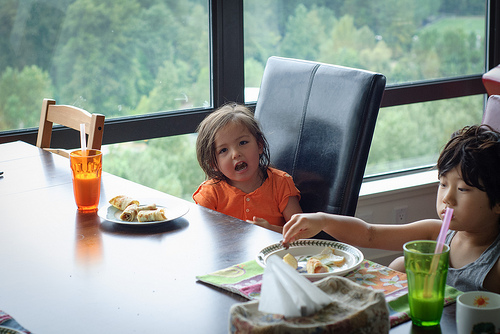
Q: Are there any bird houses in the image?
A: No, there are no bird houses.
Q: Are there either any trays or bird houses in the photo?
A: No, there are no bird houses or trays.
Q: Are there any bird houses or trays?
A: No, there are no bird houses or trays.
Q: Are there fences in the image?
A: No, there are no fences.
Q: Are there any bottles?
A: No, there are no bottles.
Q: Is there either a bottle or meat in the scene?
A: No, there are no bottles or meat.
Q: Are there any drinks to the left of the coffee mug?
A: Yes, there is a drink to the left of the coffee mug.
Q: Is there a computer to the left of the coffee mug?
A: No, there is a drink to the left of the coffee mug.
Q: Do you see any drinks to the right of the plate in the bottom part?
A: Yes, there is a drink to the right of the plate.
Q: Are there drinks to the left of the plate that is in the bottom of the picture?
A: No, the drink is to the right of the plate.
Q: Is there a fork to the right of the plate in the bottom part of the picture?
A: No, there is a drink to the right of the plate.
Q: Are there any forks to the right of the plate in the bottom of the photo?
A: No, there is a drink to the right of the plate.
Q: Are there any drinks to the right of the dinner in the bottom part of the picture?
A: Yes, there is a drink to the right of the dinner.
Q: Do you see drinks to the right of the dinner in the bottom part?
A: Yes, there is a drink to the right of the dinner.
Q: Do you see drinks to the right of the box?
A: Yes, there is a drink to the right of the box.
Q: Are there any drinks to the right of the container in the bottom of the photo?
A: Yes, there is a drink to the right of the box.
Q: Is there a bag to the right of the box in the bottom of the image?
A: No, there is a drink to the right of the box.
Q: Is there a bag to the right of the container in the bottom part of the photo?
A: No, there is a drink to the right of the box.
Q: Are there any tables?
A: Yes, there is a table.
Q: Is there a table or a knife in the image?
A: Yes, there is a table.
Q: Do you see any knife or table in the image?
A: Yes, there is a table.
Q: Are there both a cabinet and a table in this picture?
A: No, there is a table but no cabinets.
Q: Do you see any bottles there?
A: No, there are no bottles.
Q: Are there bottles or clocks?
A: No, there are no bottles or clocks.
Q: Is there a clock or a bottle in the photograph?
A: No, there are no bottles or clocks.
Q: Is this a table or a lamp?
A: This is a table.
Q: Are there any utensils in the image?
A: No, there are no utensils.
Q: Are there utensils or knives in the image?
A: No, there are no utensils or knives.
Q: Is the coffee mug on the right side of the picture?
A: Yes, the coffee mug is on the right of the image.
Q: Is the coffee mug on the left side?
A: No, the coffee mug is on the right of the image.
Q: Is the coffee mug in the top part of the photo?
A: No, the coffee mug is in the bottom of the image.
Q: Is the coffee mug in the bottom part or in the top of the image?
A: The coffee mug is in the bottom of the image.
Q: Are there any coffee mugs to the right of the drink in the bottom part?
A: Yes, there is a coffee mug to the right of the drink.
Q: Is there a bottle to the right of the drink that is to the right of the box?
A: No, there is a coffee mug to the right of the drink.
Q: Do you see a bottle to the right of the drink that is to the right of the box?
A: No, there is a coffee mug to the right of the drink.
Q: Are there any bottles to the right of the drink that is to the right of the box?
A: No, there is a coffee mug to the right of the drink.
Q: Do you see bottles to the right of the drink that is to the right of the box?
A: No, there is a coffee mug to the right of the drink.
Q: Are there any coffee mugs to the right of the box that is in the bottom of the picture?
A: Yes, there is a coffee mug to the right of the box.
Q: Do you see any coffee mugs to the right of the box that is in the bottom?
A: Yes, there is a coffee mug to the right of the box.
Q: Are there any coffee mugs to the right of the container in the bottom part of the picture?
A: Yes, there is a coffee mug to the right of the box.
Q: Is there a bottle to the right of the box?
A: No, there is a coffee mug to the right of the box.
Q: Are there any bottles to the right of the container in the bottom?
A: No, there is a coffee mug to the right of the box.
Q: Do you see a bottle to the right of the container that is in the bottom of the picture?
A: No, there is a coffee mug to the right of the box.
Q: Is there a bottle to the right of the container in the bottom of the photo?
A: No, there is a coffee mug to the right of the box.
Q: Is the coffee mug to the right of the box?
A: Yes, the coffee mug is to the right of the box.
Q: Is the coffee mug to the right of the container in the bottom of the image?
A: Yes, the coffee mug is to the right of the box.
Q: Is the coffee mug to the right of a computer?
A: No, the coffee mug is to the right of the box.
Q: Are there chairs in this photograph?
A: Yes, there is a chair.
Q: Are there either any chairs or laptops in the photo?
A: Yes, there is a chair.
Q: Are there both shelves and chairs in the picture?
A: No, there is a chair but no shelves.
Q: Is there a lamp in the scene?
A: No, there are no lamps.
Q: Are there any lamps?
A: No, there are no lamps.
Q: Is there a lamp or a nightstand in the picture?
A: No, there are no lamps or nightstands.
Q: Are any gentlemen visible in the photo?
A: No, there are no gentlemen.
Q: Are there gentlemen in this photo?
A: No, there are no gentlemen.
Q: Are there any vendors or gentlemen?
A: No, there are no gentlemen or vendors.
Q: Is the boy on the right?
A: Yes, the boy is on the right of the image.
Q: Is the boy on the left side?
A: No, the boy is on the right of the image.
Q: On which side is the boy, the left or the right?
A: The boy is on the right of the image.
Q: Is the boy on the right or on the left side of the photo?
A: The boy is on the right of the image.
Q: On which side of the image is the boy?
A: The boy is on the right of the image.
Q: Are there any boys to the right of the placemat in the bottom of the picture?
A: Yes, there is a boy to the right of the placemat.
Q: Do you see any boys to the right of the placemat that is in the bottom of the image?
A: Yes, there is a boy to the right of the placemat.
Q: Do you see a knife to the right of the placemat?
A: No, there is a boy to the right of the placemat.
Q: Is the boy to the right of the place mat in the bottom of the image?
A: Yes, the boy is to the right of the placemat.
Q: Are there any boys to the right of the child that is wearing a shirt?
A: Yes, there is a boy to the right of the child.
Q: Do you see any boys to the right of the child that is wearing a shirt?
A: Yes, there is a boy to the right of the child.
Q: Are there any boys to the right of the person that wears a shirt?
A: Yes, there is a boy to the right of the child.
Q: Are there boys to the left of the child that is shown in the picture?
A: No, the boy is to the right of the child.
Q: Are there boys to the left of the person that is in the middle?
A: No, the boy is to the right of the child.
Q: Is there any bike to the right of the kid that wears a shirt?
A: No, there is a boy to the right of the kid.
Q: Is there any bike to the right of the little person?
A: No, there is a boy to the right of the kid.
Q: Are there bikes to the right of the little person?
A: No, there is a boy to the right of the kid.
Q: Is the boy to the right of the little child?
A: Yes, the boy is to the right of the kid.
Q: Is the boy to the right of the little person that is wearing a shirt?
A: Yes, the boy is to the right of the kid.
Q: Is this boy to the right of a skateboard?
A: No, the boy is to the right of the kid.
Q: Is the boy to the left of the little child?
A: No, the boy is to the right of the kid.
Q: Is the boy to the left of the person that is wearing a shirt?
A: No, the boy is to the right of the kid.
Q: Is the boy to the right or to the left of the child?
A: The boy is to the right of the child.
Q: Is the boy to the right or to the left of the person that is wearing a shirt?
A: The boy is to the right of the child.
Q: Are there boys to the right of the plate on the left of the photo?
A: Yes, there is a boy to the right of the plate.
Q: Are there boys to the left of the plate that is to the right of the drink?
A: No, the boy is to the right of the plate.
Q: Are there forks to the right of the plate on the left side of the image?
A: No, there is a boy to the right of the plate.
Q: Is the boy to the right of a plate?
A: Yes, the boy is to the right of a plate.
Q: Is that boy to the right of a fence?
A: No, the boy is to the right of a plate.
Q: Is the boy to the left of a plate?
A: No, the boy is to the right of a plate.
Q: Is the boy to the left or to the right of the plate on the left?
A: The boy is to the right of the plate.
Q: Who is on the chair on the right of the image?
A: The boy is on the chair.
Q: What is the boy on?
A: The boy is on the chair.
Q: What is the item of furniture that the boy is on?
A: The piece of furniture is a chair.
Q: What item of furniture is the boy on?
A: The boy is on the chair.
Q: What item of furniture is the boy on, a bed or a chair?
A: The boy is on a chair.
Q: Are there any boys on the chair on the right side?
A: Yes, there is a boy on the chair.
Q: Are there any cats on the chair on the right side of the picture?
A: No, there is a boy on the chair.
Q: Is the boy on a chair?
A: Yes, the boy is on a chair.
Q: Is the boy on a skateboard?
A: No, the boy is on a chair.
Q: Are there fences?
A: No, there are no fences.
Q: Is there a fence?
A: No, there are no fences.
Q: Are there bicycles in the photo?
A: No, there are no bicycles.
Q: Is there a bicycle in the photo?
A: No, there are no bicycles.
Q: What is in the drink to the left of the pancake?
A: The straw is in the drink.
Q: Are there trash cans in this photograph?
A: No, there are no trash cans.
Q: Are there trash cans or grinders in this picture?
A: No, there are no trash cans or grinders.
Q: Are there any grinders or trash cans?
A: No, there are no trash cans or grinders.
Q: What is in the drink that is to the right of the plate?
A: The straw is in the drink.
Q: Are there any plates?
A: Yes, there is a plate.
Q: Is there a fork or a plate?
A: Yes, there is a plate.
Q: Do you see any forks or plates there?
A: Yes, there is a plate.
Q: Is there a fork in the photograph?
A: No, there are no forks.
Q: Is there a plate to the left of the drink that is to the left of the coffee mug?
A: Yes, there is a plate to the left of the drink.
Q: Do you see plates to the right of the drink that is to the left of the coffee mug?
A: No, the plate is to the left of the drink.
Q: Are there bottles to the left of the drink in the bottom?
A: No, there is a plate to the left of the drink.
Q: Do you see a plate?
A: Yes, there is a plate.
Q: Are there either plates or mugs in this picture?
A: Yes, there is a plate.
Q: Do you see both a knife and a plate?
A: No, there is a plate but no knives.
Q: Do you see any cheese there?
A: No, there is no cheese.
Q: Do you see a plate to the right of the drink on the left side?
A: Yes, there is a plate to the right of the drink.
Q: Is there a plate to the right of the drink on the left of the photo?
A: Yes, there is a plate to the right of the drink.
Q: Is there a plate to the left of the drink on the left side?
A: No, the plate is to the right of the drink.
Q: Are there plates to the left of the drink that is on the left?
A: No, the plate is to the right of the drink.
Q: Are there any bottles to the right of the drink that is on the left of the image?
A: No, there is a plate to the right of the drink.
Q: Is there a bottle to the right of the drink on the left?
A: No, there is a plate to the right of the drink.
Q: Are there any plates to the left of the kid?
A: Yes, there is a plate to the left of the kid.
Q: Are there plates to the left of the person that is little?
A: Yes, there is a plate to the left of the kid.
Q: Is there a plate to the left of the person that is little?
A: Yes, there is a plate to the left of the kid.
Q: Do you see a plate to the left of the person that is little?
A: Yes, there is a plate to the left of the kid.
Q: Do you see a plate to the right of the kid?
A: No, the plate is to the left of the kid.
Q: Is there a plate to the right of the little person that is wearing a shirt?
A: No, the plate is to the left of the kid.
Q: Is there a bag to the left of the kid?
A: No, there is a plate to the left of the kid.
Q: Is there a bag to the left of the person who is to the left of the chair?
A: No, there is a plate to the left of the kid.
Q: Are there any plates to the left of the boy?
A: Yes, there is a plate to the left of the boy.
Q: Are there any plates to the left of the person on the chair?
A: Yes, there is a plate to the left of the boy.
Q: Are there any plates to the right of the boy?
A: No, the plate is to the left of the boy.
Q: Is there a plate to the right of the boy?
A: No, the plate is to the left of the boy.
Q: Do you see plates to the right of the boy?
A: No, the plate is to the left of the boy.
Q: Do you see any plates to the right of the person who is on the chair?
A: No, the plate is to the left of the boy.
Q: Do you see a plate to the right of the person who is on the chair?
A: No, the plate is to the left of the boy.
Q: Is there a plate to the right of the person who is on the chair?
A: No, the plate is to the left of the boy.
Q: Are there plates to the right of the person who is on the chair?
A: No, the plate is to the left of the boy.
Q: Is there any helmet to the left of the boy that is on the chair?
A: No, there is a plate to the left of the boy.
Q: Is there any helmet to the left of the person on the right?
A: No, there is a plate to the left of the boy.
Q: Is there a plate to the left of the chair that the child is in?
A: Yes, there is a plate to the left of the chair.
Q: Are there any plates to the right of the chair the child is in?
A: No, the plate is to the left of the chair.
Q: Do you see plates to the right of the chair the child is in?
A: No, the plate is to the left of the chair.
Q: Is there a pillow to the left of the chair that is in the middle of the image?
A: No, there is a plate to the left of the chair.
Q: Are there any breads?
A: No, there are no breads.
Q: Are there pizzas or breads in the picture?
A: No, there are no breads or pizzas.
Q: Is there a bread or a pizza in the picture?
A: No, there are no breads or pizzas.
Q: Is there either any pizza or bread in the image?
A: No, there are no breads or pizzas.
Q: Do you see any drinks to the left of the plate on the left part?
A: Yes, there is a drink to the left of the plate.